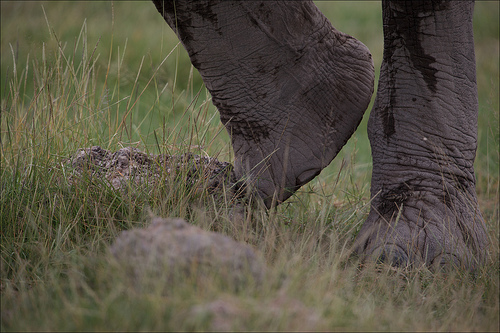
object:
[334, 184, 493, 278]
foot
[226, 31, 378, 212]
foot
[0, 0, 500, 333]
grass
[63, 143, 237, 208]
rock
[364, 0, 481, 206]
leg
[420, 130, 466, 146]
fold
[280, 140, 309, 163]
wrinkles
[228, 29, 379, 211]
hooves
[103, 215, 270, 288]
rock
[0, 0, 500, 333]
field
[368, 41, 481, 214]
skin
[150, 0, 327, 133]
leg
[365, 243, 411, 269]
toe nail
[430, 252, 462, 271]
toe nail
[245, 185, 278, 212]
toe nail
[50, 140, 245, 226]
mound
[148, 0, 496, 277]
elephant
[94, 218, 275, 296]
mounds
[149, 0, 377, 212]
skin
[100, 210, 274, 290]
dirt